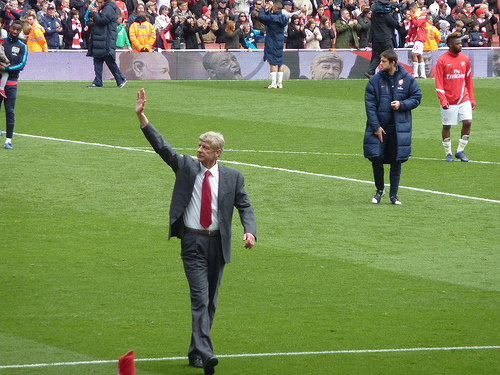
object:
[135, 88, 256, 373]
man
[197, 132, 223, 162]
head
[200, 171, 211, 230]
tie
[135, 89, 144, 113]
hand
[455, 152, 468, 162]
shoes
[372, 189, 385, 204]
shoes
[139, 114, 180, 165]
arm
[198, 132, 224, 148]
hair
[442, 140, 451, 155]
socks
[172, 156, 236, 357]
suit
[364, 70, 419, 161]
coat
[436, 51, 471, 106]
shirt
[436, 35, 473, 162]
man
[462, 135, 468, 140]
shin guards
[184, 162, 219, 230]
shirt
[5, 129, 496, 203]
lines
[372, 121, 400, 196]
pants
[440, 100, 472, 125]
shorts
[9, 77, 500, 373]
field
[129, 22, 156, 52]
jacket